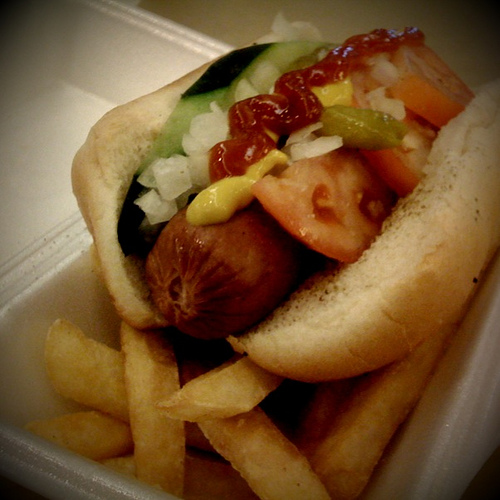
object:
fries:
[23, 317, 462, 499]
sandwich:
[70, 8, 496, 383]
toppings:
[133, 14, 473, 227]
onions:
[132, 100, 230, 227]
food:
[21, 25, 497, 500]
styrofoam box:
[0, 0, 500, 500]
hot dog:
[141, 212, 300, 340]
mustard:
[311, 76, 354, 109]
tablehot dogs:
[71, 8, 499, 384]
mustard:
[186, 148, 293, 227]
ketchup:
[249, 44, 474, 264]